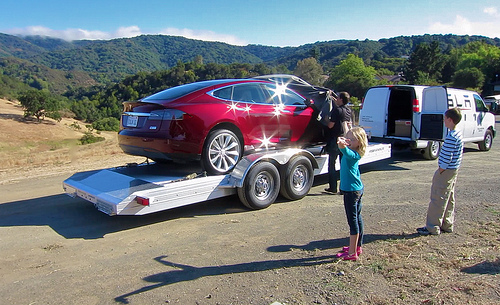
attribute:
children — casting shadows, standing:
[327, 109, 465, 265]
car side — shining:
[172, 80, 342, 171]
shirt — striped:
[438, 130, 465, 171]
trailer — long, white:
[63, 143, 392, 220]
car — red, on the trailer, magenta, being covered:
[118, 76, 348, 174]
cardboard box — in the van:
[395, 119, 413, 139]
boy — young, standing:
[417, 108, 464, 235]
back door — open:
[358, 86, 450, 146]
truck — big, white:
[357, 85, 495, 160]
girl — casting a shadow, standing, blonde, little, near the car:
[334, 128, 369, 263]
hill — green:
[1, 32, 500, 93]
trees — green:
[7, 37, 496, 91]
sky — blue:
[1, 0, 498, 37]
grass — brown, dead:
[270, 220, 499, 304]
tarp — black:
[253, 73, 338, 155]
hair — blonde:
[343, 126, 368, 156]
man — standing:
[323, 92, 353, 195]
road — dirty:
[11, 138, 499, 299]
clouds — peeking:
[2, 11, 499, 46]